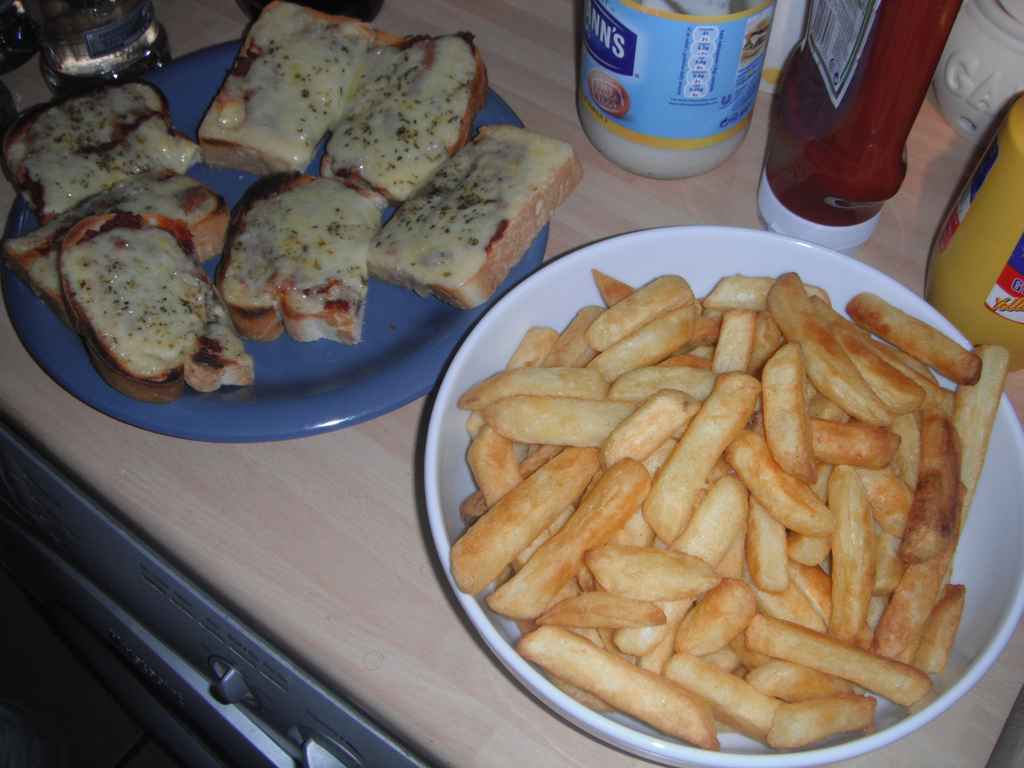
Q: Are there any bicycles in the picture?
A: No, there are no bicycles.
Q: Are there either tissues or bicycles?
A: No, there are no bicycles or tissues.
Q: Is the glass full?
A: Yes, the glass is full.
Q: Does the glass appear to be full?
A: Yes, the glass is full.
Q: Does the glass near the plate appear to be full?
A: Yes, the glass is full.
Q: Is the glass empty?
A: No, the glass is full.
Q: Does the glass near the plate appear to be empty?
A: No, the glass is full.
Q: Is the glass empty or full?
A: The glass is full.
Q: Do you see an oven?
A: Yes, there is an oven.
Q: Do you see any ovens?
A: Yes, there is an oven.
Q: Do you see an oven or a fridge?
A: Yes, there is an oven.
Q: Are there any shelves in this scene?
A: No, there are no shelves.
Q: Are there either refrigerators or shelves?
A: No, there are no shelves or refrigerators.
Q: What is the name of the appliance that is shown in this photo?
A: The appliance is an oven.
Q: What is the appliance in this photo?
A: The appliance is an oven.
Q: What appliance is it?
A: The appliance is an oven.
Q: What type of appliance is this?
A: This is an oven.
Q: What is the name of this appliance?
A: This is an oven.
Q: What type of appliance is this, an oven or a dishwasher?
A: This is an oven.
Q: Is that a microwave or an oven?
A: That is an oven.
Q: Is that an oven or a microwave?
A: That is an oven.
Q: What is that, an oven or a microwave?
A: That is an oven.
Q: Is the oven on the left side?
A: Yes, the oven is on the left of the image.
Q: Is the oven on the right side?
A: No, the oven is on the left of the image.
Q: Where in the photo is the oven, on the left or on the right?
A: The oven is on the left of the image.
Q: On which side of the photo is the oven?
A: The oven is on the left of the image.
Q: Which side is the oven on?
A: The oven is on the left of the image.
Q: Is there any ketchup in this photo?
A: Yes, there is ketchup.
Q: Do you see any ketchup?
A: Yes, there is ketchup.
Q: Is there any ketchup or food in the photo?
A: Yes, there is ketchup.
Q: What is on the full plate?
A: The ketchup is on the plate.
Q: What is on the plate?
A: The ketchup is on the plate.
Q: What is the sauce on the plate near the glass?
A: The sauce is ketchup.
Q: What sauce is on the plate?
A: The sauce is ketchup.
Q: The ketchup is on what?
A: The ketchup is on the plate.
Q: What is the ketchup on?
A: The ketchup is on the plate.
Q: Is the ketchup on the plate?
A: Yes, the ketchup is on the plate.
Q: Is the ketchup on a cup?
A: No, the ketchup is on the plate.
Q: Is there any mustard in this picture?
A: Yes, there is mustard.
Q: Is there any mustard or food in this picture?
A: Yes, there is mustard.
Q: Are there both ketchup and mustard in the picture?
A: Yes, there are both mustard and ketchup.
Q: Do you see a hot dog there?
A: No, there are no hot dogs.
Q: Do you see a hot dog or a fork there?
A: No, there are no hot dogs or forks.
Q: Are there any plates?
A: Yes, there is a plate.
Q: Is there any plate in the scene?
A: Yes, there is a plate.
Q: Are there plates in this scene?
A: Yes, there is a plate.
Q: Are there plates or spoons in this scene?
A: Yes, there is a plate.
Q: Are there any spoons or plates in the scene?
A: Yes, there is a plate.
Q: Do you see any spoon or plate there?
A: Yes, there is a plate.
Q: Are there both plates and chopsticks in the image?
A: No, there is a plate but no chopsticks.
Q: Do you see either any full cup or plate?
A: Yes, there is a full plate.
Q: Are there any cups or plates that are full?
A: Yes, the plate is full.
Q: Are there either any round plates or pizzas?
A: Yes, there is a round plate.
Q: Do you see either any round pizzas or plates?
A: Yes, there is a round plate.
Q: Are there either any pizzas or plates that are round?
A: Yes, the plate is round.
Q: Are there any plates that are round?
A: Yes, there is a round plate.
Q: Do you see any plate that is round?
A: Yes, there is a plate that is round.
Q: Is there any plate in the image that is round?
A: Yes, there is a plate that is round.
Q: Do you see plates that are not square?
A: Yes, there is a round plate.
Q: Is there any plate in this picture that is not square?
A: Yes, there is a round plate.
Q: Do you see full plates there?
A: Yes, there is a full plate.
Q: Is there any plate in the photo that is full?
A: Yes, there is a plate that is full.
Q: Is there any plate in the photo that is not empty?
A: Yes, there is an full plate.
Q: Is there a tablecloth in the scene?
A: No, there are no tablecloths.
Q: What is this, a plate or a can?
A: This is a plate.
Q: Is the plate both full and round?
A: Yes, the plate is full and round.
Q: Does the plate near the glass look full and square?
A: No, the plate is full but round.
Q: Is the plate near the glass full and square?
A: No, the plate is full but round.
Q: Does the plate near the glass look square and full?
A: No, the plate is full but round.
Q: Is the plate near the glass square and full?
A: No, the plate is full but round.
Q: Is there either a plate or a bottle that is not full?
A: No, there is a plate but it is full.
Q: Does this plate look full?
A: Yes, the plate is full.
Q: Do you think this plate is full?
A: Yes, the plate is full.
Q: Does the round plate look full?
A: Yes, the plate is full.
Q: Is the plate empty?
A: No, the plate is full.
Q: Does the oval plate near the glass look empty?
A: No, the plate is full.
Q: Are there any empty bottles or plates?
A: No, there is a plate but it is full.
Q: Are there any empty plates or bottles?
A: No, there is a plate but it is full.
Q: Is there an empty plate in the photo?
A: No, there is a plate but it is full.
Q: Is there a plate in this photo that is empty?
A: No, there is a plate but it is full.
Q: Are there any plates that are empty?
A: No, there is a plate but it is full.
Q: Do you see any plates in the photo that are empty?
A: No, there is a plate but it is full.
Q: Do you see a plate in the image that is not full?
A: No, there is a plate but it is full.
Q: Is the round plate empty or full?
A: The plate is full.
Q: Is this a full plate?
A: Yes, this is a full plate.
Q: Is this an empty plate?
A: No, this is a full plate.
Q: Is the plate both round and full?
A: Yes, the plate is round and full.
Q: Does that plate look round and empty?
A: No, the plate is round but full.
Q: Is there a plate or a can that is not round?
A: No, there is a plate but it is round.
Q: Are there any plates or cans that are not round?
A: No, there is a plate but it is round.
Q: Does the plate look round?
A: Yes, the plate is round.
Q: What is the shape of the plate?
A: The plate is round.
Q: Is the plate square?
A: No, the plate is round.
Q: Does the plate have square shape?
A: No, the plate is round.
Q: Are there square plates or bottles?
A: No, there is a plate but it is round.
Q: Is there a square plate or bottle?
A: No, there is a plate but it is round.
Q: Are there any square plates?
A: No, there is a plate but it is round.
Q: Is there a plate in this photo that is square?
A: No, there is a plate but it is round.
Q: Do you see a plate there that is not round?
A: No, there is a plate but it is round.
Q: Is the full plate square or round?
A: The plate is round.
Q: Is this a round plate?
A: Yes, this is a round plate.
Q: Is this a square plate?
A: No, this is a round plate.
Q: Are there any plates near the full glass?
A: Yes, there is a plate near the glass.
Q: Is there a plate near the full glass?
A: Yes, there is a plate near the glass.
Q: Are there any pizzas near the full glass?
A: No, there is a plate near the glass.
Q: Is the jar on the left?
A: No, the jar is on the right of the image.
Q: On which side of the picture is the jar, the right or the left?
A: The jar is on the right of the image.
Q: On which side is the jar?
A: The jar is on the right of the image.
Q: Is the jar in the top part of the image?
A: Yes, the jar is in the top of the image.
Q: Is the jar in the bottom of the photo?
A: No, the jar is in the top of the image.